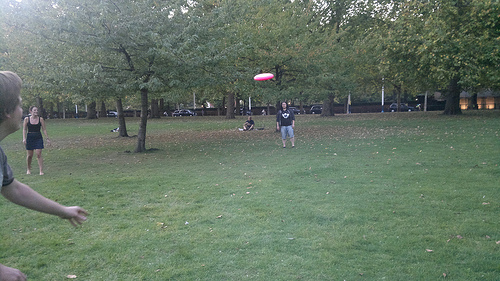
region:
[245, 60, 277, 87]
red frisby in air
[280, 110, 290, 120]
white symbol on shirt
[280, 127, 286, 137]
women wearing blue jeans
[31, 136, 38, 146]
woman wearing blue skirt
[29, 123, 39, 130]
woman wearing black shirt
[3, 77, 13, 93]
man has brown hair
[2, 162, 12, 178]
man has grey shirt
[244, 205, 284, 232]
green grass in field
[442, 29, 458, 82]
tall tree in park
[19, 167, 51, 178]
womans bare feet in grass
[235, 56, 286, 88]
red frisbee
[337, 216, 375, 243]
short green and brown grass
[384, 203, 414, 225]
short green and brown grass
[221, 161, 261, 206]
short green and brown grass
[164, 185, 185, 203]
short green and brown grass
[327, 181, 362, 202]
short green and brown grass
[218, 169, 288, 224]
short green and brown grass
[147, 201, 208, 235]
short green and brown grass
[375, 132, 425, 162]
short green and brown grass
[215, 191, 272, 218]
short green and brown grass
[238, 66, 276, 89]
frisbee flying through the air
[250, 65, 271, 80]
frisbee is red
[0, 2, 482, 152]
several trees in the park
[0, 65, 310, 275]
two men playing frisbee with each other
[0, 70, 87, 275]
man has hands out to catch frisbee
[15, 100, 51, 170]
female spectator watching them play soccer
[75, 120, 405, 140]
leaves that have fallen on the ground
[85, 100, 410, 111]
cars parked along the street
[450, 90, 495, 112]
a tent with lights glowing at right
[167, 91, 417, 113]
a brick wall on the opposite side of the street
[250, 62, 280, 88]
frisbee in the air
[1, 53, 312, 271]
people playing with frisbee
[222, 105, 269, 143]
person sitting on grass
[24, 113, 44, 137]
woman wearing a black shirt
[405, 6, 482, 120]
tall green leafy tree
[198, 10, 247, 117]
tall green leafy tree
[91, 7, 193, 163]
tall green leafy tree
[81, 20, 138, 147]
tall green leafy tree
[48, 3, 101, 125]
tall green leafy tree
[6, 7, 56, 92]
tall green leafy tree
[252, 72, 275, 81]
pink plastic frisbee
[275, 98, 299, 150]
man in black shirt waiting for frisbee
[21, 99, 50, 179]
woman in black dress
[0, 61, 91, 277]
man on left with arm reaching out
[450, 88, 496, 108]
well-lit building in background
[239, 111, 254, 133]
person sitting on blanket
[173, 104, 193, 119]
black car in background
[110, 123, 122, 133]
black and white dog behind tree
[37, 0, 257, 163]
two trees in park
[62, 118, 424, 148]
fallen leaves on ground